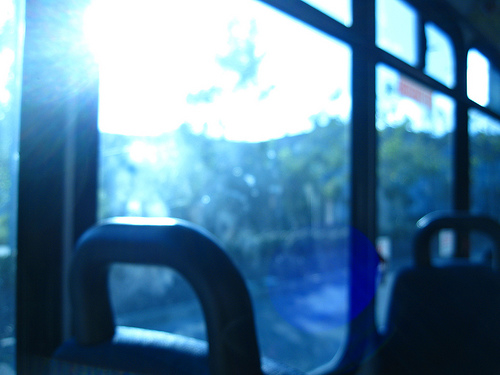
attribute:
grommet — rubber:
[330, 337, 352, 369]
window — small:
[467, 46, 499, 117]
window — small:
[421, 18, 456, 92]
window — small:
[370, 0, 424, 70]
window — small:
[255, 0, 355, 33]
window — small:
[368, 47, 463, 350]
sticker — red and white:
[396, 64, 433, 112]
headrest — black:
[68, 214, 263, 366]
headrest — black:
[409, 209, 499, 271]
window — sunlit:
[4, 0, 496, 279]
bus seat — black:
[381, 218, 498, 370]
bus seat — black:
[42, 216, 267, 371]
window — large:
[91, 2, 367, 363]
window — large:
[359, 49, 466, 282]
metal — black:
[352, 3, 376, 360]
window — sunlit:
[98, 0, 350, 368]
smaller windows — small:
[303, 1, 355, 28]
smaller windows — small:
[370, 0, 418, 70]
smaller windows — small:
[424, 21, 456, 92]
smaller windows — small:
[463, 44, 498, 101]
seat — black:
[57, 213, 265, 372]